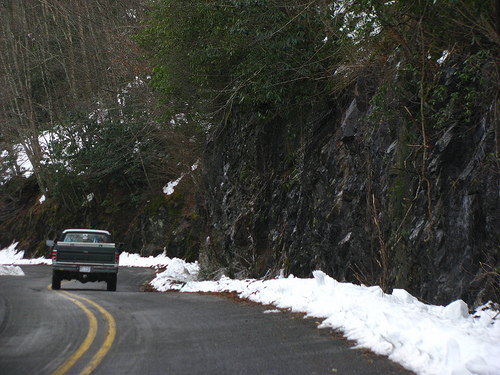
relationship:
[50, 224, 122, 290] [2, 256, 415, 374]
truck on road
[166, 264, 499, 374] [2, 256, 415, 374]
snow along road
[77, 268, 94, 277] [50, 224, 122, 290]
license plate on back part of truck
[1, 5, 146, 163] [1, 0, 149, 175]
trees doesnt have leaves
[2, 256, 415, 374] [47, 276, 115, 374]
road have lines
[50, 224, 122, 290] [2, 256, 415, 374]
car on road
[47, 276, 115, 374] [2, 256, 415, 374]
lines are on road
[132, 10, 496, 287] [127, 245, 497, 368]
trees are in sides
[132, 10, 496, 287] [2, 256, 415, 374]
trees side of road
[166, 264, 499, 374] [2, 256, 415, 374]
snow on side of road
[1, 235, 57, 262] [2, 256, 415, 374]
snow on side of road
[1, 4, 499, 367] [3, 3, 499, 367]
picture taked on daytime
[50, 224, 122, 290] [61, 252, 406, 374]
truck on right road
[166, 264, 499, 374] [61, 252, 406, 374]
snow on right road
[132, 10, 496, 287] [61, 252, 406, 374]
mountain on right road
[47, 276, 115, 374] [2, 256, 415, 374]
lines on center of road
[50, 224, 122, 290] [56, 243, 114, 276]
truck has space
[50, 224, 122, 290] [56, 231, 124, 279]
truck have load on back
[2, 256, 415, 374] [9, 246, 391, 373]
road doesnt have snow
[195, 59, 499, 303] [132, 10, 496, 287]
rocks have bushes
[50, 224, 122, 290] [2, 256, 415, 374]
truck rolling on road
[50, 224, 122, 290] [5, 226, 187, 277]
truck going downhill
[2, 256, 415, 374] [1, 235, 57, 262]
road cleared of snow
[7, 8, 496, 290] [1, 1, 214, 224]
forest are on top of cliff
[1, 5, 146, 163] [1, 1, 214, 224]
trees are over a cliff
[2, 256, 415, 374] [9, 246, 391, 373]
road after snowing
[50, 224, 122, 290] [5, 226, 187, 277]
truck going to downhill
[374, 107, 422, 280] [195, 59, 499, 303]
vines over rocks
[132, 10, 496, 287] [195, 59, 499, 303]
trees over rocks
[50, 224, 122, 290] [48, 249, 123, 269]
truck doesnt have braking lights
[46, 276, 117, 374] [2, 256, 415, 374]
yellow line painted on road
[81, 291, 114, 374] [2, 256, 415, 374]
yellow line painted on road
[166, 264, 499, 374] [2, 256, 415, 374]
snow at side of road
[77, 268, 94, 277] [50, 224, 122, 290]
license plate on back of truck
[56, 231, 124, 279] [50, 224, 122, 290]
bed gate on back of truck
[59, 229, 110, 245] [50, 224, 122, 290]
windshield of a truck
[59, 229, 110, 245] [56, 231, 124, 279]
windshield on back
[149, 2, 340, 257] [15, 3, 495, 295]
tree on a hillside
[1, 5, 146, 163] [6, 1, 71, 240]
trees on left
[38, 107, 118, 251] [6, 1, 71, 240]
trees on left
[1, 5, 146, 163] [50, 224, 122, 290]
trees above truck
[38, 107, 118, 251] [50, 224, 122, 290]
trees above truck